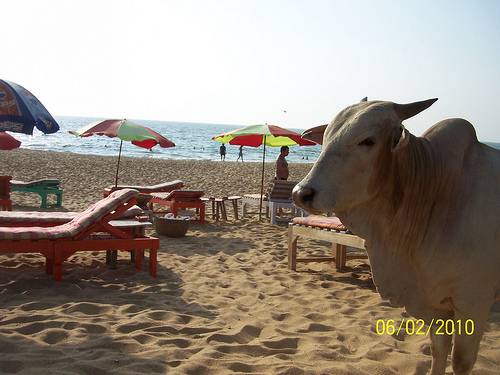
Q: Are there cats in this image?
A: No, there are no cats.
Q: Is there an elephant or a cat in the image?
A: No, there are no cats or elephants.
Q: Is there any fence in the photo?
A: No, there are no fences.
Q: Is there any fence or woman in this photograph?
A: No, there are no fences or women.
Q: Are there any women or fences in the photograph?
A: No, there are no fences or women.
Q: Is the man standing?
A: Yes, the man is standing.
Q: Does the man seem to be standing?
A: Yes, the man is standing.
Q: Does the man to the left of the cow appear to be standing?
A: Yes, the man is standing.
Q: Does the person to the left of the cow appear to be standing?
A: Yes, the man is standing.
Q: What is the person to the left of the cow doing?
A: The man is standing.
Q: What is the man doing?
A: The man is standing.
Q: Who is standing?
A: The man is standing.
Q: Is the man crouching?
A: No, the man is standing.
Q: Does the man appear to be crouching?
A: No, the man is standing.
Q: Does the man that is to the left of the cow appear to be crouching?
A: No, the man is standing.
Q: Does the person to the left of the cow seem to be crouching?
A: No, the man is standing.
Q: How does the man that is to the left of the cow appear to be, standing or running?
A: The man is standing.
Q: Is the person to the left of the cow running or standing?
A: The man is standing.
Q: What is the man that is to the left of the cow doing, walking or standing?
A: The man is standing.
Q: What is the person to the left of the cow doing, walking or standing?
A: The man is standing.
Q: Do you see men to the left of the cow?
A: Yes, there is a man to the left of the cow.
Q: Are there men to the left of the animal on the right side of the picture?
A: Yes, there is a man to the left of the cow.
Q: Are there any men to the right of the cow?
A: No, the man is to the left of the cow.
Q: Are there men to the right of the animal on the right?
A: No, the man is to the left of the cow.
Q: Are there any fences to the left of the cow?
A: No, there is a man to the left of the cow.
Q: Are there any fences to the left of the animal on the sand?
A: No, there is a man to the left of the cow.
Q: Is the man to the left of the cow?
A: Yes, the man is to the left of the cow.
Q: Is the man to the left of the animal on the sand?
A: Yes, the man is to the left of the cow.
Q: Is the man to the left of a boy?
A: No, the man is to the left of the cow.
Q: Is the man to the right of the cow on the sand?
A: No, the man is to the left of the cow.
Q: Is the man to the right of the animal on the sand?
A: No, the man is to the left of the cow.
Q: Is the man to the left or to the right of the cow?
A: The man is to the left of the cow.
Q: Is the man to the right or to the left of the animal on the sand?
A: The man is to the left of the cow.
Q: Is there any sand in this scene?
A: Yes, there is sand.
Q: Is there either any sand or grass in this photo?
A: Yes, there is sand.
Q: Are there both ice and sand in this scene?
A: No, there is sand but no ice.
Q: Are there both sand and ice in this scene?
A: No, there is sand but no ice.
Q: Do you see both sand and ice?
A: No, there is sand but no ice.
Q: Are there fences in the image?
A: No, there are no fences.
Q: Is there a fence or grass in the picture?
A: No, there are no fences or grass.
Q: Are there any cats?
A: No, there are no cats.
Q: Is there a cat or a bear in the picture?
A: No, there are no cats or bears.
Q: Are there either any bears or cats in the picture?
A: No, there are no cats or bears.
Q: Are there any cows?
A: Yes, there is a cow.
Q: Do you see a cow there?
A: Yes, there is a cow.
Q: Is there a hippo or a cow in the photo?
A: Yes, there is a cow.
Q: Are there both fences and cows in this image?
A: No, there is a cow but no fences.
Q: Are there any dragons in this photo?
A: No, there are no dragons.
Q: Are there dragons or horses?
A: No, there are no dragons or horses.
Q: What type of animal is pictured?
A: The animal is a cow.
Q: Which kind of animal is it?
A: The animal is a cow.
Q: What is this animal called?
A: This is a cow.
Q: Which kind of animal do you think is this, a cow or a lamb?
A: This is a cow.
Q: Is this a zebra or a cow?
A: This is a cow.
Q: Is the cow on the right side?
A: Yes, the cow is on the right of the image.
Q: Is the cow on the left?
A: No, the cow is on the right of the image.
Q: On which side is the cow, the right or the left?
A: The cow is on the right of the image.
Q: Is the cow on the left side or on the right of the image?
A: The cow is on the right of the image.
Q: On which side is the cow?
A: The cow is on the right of the image.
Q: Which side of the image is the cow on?
A: The cow is on the right of the image.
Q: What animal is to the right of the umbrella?
A: The animal is a cow.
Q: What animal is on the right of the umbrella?
A: The animal is a cow.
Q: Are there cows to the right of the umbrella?
A: Yes, there is a cow to the right of the umbrella.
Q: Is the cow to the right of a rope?
A: No, the cow is to the right of the umbrella.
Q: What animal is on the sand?
A: The cow is on the sand.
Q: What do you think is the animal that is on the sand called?
A: The animal is a cow.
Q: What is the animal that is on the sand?
A: The animal is a cow.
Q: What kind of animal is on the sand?
A: The animal is a cow.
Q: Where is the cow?
A: The cow is on the sand.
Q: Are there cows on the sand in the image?
A: Yes, there is a cow on the sand.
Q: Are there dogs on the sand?
A: No, there is a cow on the sand.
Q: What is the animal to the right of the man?
A: The animal is a cow.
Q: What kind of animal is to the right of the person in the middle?
A: The animal is a cow.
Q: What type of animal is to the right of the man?
A: The animal is a cow.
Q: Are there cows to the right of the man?
A: Yes, there is a cow to the right of the man.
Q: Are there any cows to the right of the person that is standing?
A: Yes, there is a cow to the right of the man.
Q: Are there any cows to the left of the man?
A: No, the cow is to the right of the man.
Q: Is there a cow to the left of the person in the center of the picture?
A: No, the cow is to the right of the man.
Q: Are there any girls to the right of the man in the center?
A: No, there is a cow to the right of the man.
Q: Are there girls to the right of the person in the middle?
A: No, there is a cow to the right of the man.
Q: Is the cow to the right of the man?
A: Yes, the cow is to the right of the man.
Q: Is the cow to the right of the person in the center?
A: Yes, the cow is to the right of the man.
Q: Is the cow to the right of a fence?
A: No, the cow is to the right of the man.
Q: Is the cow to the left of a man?
A: No, the cow is to the right of a man.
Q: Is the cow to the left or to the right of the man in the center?
A: The cow is to the right of the man.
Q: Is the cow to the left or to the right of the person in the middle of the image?
A: The cow is to the right of the man.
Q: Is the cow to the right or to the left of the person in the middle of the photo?
A: The cow is to the right of the man.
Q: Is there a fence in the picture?
A: No, there are no fences.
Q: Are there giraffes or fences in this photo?
A: No, there are no fences or giraffes.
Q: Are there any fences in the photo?
A: No, there are no fences.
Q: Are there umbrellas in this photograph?
A: Yes, there is an umbrella.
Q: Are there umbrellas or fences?
A: Yes, there is an umbrella.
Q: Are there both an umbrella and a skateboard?
A: No, there is an umbrella but no skateboards.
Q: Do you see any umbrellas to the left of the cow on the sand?
A: Yes, there is an umbrella to the left of the cow.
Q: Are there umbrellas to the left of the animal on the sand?
A: Yes, there is an umbrella to the left of the cow.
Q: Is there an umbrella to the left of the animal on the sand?
A: Yes, there is an umbrella to the left of the cow.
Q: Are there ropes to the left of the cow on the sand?
A: No, there is an umbrella to the left of the cow.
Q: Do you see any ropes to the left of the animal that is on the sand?
A: No, there is an umbrella to the left of the cow.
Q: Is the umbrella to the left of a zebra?
A: No, the umbrella is to the left of the cow.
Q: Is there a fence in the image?
A: No, there are no fences.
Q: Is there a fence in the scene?
A: No, there are no fences.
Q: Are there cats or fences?
A: No, there are no fences or cats.